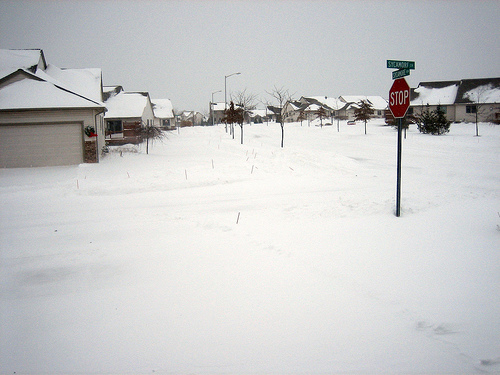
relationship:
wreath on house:
[81, 120, 96, 141] [13, 116, 74, 168]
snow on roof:
[49, 90, 53, 95] [21, 66, 36, 74]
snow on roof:
[127, 105, 149, 111] [115, 84, 120, 86]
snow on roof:
[442, 96, 452, 108] [435, 79, 449, 87]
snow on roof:
[324, 100, 339, 106] [323, 94, 329, 95]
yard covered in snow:
[77, 229, 443, 347] [103, 234, 131, 248]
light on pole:
[237, 68, 247, 78] [224, 89, 230, 102]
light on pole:
[216, 88, 224, 94] [211, 109, 216, 131]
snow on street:
[438, 355, 444, 357] [282, 353, 441, 369]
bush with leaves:
[424, 116, 451, 132] [427, 110, 428, 113]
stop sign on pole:
[397, 92, 407, 107] [397, 141, 402, 195]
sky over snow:
[182, 11, 447, 36] [103, 234, 131, 248]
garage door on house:
[9, 155, 61, 161] [13, 116, 74, 168]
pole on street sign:
[224, 89, 230, 102] [395, 59, 409, 67]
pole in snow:
[224, 89, 230, 102] [103, 234, 131, 248]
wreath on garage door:
[81, 120, 96, 141] [9, 155, 61, 161]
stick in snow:
[237, 212, 241, 220] [103, 234, 131, 248]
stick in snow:
[182, 166, 192, 184] [103, 234, 131, 248]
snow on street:
[103, 234, 131, 248] [282, 353, 441, 369]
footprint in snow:
[420, 317, 458, 340] [103, 234, 131, 248]